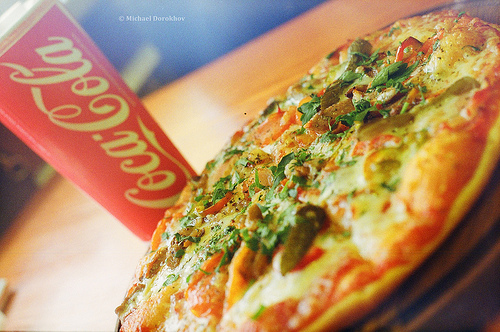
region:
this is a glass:
[4, 0, 211, 241]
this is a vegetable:
[311, 98, 381, 143]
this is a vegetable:
[252, 218, 277, 254]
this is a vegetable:
[190, 233, 239, 268]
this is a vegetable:
[191, 167, 268, 247]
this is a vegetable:
[265, 144, 315, 194]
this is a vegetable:
[361, 64, 418, 117]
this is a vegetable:
[286, 73, 362, 143]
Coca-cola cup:
[8, 6, 212, 250]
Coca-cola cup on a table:
[4, 2, 187, 228]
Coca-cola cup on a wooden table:
[8, 7, 205, 226]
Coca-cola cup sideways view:
[2, 7, 191, 219]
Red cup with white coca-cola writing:
[3, 7, 189, 235]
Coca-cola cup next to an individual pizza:
[5, 2, 491, 323]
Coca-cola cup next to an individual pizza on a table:
[11, 6, 492, 322]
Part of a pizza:
[197, 24, 499, 328]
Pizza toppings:
[237, 133, 498, 318]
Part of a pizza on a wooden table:
[203, 6, 499, 329]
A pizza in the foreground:
[106, 5, 496, 328]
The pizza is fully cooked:
[111, 0, 495, 329]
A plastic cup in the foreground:
[2, 4, 213, 259]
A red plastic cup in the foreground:
[0, 5, 212, 246]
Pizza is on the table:
[1, 1, 498, 330]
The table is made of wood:
[3, 0, 496, 330]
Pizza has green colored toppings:
[158, 22, 499, 323]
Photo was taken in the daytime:
[1, 1, 498, 330]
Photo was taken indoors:
[1, 3, 498, 330]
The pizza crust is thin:
[106, 5, 499, 327]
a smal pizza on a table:
[68, 3, 496, 275]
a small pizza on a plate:
[196, 40, 461, 289]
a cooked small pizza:
[155, 64, 357, 297]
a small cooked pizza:
[153, 87, 433, 327]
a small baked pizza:
[175, 106, 478, 323]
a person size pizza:
[244, 51, 468, 283]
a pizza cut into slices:
[197, 51, 421, 328]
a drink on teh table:
[26, 4, 263, 299]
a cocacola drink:
[10, 1, 237, 261]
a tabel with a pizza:
[107, 33, 447, 319]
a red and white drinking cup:
[1, 3, 211, 252]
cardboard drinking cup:
[1, 3, 209, 251]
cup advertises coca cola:
[1, 3, 212, 243]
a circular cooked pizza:
[97, 10, 498, 330]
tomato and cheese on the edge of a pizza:
[388, 99, 492, 259]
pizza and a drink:
[3, 8, 498, 329]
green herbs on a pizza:
[222, 149, 340, 251]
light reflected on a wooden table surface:
[30, 81, 242, 328]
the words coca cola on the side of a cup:
[5, 40, 195, 218]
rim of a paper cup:
[0, 0, 45, 50]